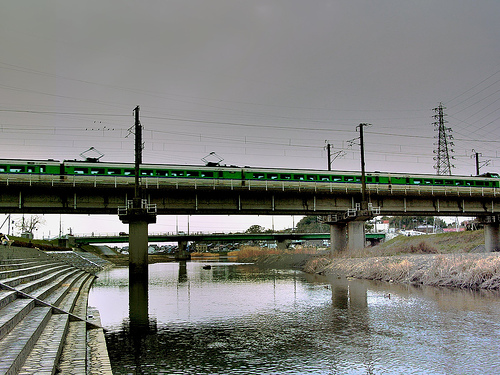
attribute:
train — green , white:
[29, 148, 493, 205]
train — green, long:
[3, 158, 497, 194]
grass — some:
[364, 226, 484, 255]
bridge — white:
[1, 151, 498, 262]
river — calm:
[97, 259, 499, 372]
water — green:
[222, 306, 345, 366]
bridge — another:
[33, 224, 383, 247]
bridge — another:
[5, 158, 499, 223]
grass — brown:
[294, 253, 499, 290]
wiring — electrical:
[2, 103, 499, 175]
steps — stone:
[0, 246, 115, 373]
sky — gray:
[0, 1, 497, 111]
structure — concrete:
[4, 243, 107, 371]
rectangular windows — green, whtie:
[48, 152, 470, 201]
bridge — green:
[11, 137, 444, 245]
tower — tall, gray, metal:
[434, 102, 459, 174]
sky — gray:
[2, 144, 499, 215]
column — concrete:
[128, 224, 147, 321]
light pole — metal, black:
[355, 121, 370, 208]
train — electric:
[45, 114, 490, 204]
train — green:
[3, 166, 493, 206]